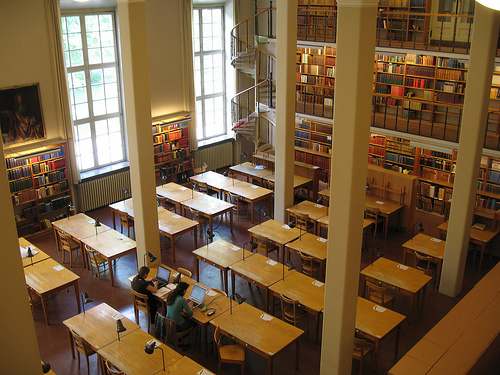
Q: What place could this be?
A: It is a library.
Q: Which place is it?
A: It is a library.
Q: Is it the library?
A: Yes, it is the library.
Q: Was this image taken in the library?
A: Yes, it was taken in the library.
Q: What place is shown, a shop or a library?
A: It is a library.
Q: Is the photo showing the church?
A: No, the picture is showing the library.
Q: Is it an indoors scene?
A: Yes, it is indoors.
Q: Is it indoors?
A: Yes, it is indoors.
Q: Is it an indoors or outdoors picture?
A: It is indoors.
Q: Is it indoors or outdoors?
A: It is indoors.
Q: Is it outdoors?
A: No, it is indoors.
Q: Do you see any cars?
A: No, there are no cars.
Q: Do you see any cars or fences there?
A: No, there are no cars or fences.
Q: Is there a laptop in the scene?
A: Yes, there is a laptop.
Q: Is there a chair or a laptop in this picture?
A: Yes, there is a laptop.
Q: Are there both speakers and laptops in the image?
A: No, there is a laptop but no speakers.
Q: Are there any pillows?
A: No, there are no pillows.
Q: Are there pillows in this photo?
A: No, there are no pillows.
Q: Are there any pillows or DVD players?
A: No, there are no pillows or DVD players.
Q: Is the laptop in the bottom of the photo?
A: Yes, the laptop is in the bottom of the image.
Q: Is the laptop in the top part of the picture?
A: No, the laptop is in the bottom of the image.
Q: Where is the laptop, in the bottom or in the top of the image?
A: The laptop is in the bottom of the image.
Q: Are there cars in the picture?
A: No, there are no cars.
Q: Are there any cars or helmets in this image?
A: No, there are no cars or helmets.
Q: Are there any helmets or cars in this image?
A: No, there are no cars or helmets.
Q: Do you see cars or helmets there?
A: No, there are no cars or helmets.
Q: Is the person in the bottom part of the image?
A: Yes, the person is in the bottom of the image.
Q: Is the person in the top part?
A: No, the person is in the bottom of the image.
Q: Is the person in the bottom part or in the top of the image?
A: The person is in the bottom of the image.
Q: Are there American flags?
A: No, there are no American flags.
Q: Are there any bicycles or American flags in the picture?
A: No, there are no American flags or bicycles.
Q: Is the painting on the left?
A: Yes, the painting is on the left of the image.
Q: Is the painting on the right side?
A: No, the painting is on the left of the image.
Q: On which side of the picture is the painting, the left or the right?
A: The painting is on the left of the image.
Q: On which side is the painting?
A: The painting is on the left of the image.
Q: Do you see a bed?
A: No, there are no beds.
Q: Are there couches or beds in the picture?
A: No, there are no beds or couches.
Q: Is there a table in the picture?
A: Yes, there is a table.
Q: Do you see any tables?
A: Yes, there is a table.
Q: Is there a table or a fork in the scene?
A: Yes, there is a table.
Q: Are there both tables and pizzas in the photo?
A: No, there is a table but no pizzas.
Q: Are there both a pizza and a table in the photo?
A: No, there is a table but no pizzas.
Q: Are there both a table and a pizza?
A: No, there is a table but no pizzas.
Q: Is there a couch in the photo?
A: No, there are no couches.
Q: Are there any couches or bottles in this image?
A: No, there are no couches or bottles.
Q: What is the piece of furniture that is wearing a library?
A: The piece of furniture is a table.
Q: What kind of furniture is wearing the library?
A: The piece of furniture is a table.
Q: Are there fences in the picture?
A: No, there are no fences.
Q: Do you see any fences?
A: No, there are no fences.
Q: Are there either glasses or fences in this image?
A: No, there are no fences or glasses.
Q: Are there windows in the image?
A: Yes, there is a window.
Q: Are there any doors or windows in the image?
A: Yes, there is a window.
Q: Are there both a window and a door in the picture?
A: No, there is a window but no doors.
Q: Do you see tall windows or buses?
A: Yes, there is a tall window.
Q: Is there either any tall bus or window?
A: Yes, there is a tall window.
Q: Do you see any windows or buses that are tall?
A: Yes, the window is tall.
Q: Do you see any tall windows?
A: Yes, there is a tall window.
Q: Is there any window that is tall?
A: Yes, there is a window that is tall.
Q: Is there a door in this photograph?
A: No, there are no doors.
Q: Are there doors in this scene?
A: No, there are no doors.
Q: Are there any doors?
A: No, there are no doors.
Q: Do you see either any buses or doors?
A: No, there are no doors or buses.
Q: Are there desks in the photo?
A: Yes, there is a desk.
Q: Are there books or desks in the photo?
A: Yes, there is a desk.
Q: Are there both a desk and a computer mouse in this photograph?
A: No, there is a desk but no computer mice.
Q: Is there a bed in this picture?
A: No, there are no beds.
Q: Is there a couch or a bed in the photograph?
A: No, there are no beds or couches.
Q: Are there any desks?
A: Yes, there is a desk.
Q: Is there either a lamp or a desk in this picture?
A: Yes, there is a desk.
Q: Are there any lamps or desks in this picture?
A: Yes, there is a desk.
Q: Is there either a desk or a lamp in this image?
A: Yes, there is a desk.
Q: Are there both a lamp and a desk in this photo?
A: Yes, there are both a desk and a lamp.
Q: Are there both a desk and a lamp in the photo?
A: Yes, there are both a desk and a lamp.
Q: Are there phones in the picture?
A: No, there are no phones.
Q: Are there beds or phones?
A: No, there are no phones or beds.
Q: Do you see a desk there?
A: Yes, there is a desk.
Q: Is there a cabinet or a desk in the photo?
A: Yes, there is a desk.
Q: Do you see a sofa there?
A: No, there are no sofas.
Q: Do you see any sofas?
A: No, there are no sofas.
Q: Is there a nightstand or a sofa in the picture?
A: No, there are no sofas or nightstands.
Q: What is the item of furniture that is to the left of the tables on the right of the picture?
A: The piece of furniture is a desk.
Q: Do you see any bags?
A: No, there are no bags.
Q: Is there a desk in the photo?
A: Yes, there is a desk.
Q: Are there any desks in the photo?
A: Yes, there is a desk.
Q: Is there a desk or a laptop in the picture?
A: Yes, there is a desk.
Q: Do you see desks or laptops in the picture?
A: Yes, there is a desk.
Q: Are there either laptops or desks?
A: Yes, there is a desk.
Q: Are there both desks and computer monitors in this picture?
A: No, there is a desk but no computer monitors.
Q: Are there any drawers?
A: No, there are no drawers.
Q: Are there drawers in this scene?
A: No, there are no drawers.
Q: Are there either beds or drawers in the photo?
A: No, there are no drawers or beds.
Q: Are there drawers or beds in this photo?
A: No, there are no drawers or beds.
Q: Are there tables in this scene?
A: Yes, there is a table.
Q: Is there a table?
A: Yes, there is a table.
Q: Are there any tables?
A: Yes, there is a table.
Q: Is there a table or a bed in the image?
A: Yes, there is a table.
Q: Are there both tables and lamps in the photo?
A: Yes, there are both a table and a lamp.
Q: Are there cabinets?
A: No, there are no cabinets.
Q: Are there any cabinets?
A: No, there are no cabinets.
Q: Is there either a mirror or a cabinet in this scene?
A: No, there are no cabinets or mirrors.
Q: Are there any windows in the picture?
A: Yes, there are windows.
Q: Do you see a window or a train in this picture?
A: Yes, there are windows.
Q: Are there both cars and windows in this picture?
A: No, there are windows but no cars.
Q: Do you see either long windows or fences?
A: Yes, there are long windows.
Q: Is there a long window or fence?
A: Yes, there are long windows.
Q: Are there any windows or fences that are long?
A: Yes, the windows are long.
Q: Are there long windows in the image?
A: Yes, there are long windows.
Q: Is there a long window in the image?
A: Yes, there are long windows.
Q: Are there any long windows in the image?
A: Yes, there are long windows.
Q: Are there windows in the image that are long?
A: Yes, there are windows that are long.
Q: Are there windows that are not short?
A: Yes, there are long windows.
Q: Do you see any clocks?
A: No, there are no clocks.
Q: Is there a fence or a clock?
A: No, there are no clocks or fences.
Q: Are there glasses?
A: No, there are no glasses.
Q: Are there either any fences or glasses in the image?
A: No, there are no glasses or fences.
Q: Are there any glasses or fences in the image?
A: No, there are no glasses or fences.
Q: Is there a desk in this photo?
A: Yes, there is a desk.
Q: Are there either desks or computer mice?
A: Yes, there is a desk.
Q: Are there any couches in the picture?
A: No, there are no couches.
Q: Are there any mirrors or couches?
A: No, there are no couches or mirrors.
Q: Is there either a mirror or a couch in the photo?
A: No, there are no couches or mirrors.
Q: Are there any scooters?
A: No, there are no scooters.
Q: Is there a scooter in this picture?
A: No, there are no scooters.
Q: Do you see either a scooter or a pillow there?
A: No, there are no scooters or pillows.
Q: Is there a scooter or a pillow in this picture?
A: No, there are no scooters or pillows.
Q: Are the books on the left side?
A: Yes, the books are on the left of the image.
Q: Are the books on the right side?
A: No, the books are on the left of the image.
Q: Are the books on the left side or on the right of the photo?
A: The books are on the left of the image.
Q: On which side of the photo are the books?
A: The books are on the left of the image.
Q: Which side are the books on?
A: The books are on the left of the image.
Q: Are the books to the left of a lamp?
A: Yes, the books are to the left of a lamp.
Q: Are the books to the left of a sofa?
A: No, the books are to the left of a lamp.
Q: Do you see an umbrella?
A: No, there are no umbrellas.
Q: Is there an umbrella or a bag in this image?
A: No, there are no umbrellas or bags.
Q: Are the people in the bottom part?
A: Yes, the people are in the bottom of the image.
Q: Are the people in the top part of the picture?
A: No, the people are in the bottom of the image.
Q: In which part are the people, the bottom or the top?
A: The people are in the bottom of the image.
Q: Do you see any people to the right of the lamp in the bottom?
A: Yes, there are people to the right of the lamp.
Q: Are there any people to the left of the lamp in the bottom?
A: No, the people are to the right of the lamp.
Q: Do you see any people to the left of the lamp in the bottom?
A: No, the people are to the right of the lamp.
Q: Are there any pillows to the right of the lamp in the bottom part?
A: No, there are people to the right of the lamp.